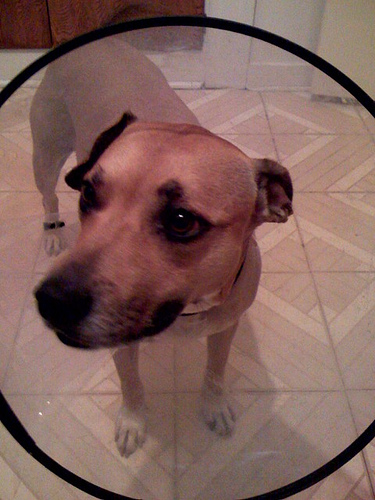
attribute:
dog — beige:
[30, 34, 293, 460]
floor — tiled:
[2, 82, 375, 498]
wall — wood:
[0, 2, 311, 86]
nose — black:
[32, 282, 87, 324]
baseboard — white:
[250, 58, 314, 93]